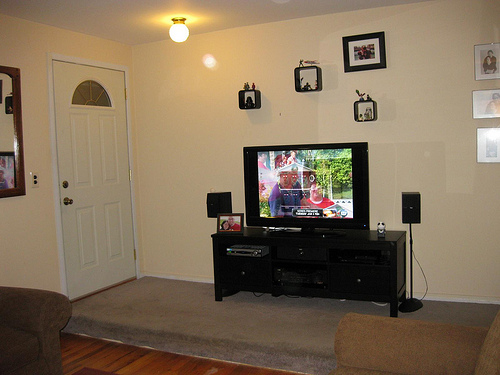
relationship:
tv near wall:
[243, 143, 369, 234] [133, 1, 498, 303]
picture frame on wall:
[340, 31, 387, 71] [133, 1, 498, 303]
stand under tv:
[210, 231, 408, 317] [243, 143, 369, 234]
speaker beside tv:
[401, 191, 423, 312] [243, 143, 369, 234]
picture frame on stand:
[216, 213, 243, 236] [210, 231, 408, 317]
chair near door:
[2, 286, 71, 374] [54, 61, 138, 300]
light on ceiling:
[169, 16, 191, 44] [1, 1, 414, 43]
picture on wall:
[474, 42, 500, 80] [133, 1, 498, 303]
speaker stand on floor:
[405, 225, 422, 312] [60, 275, 497, 374]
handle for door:
[65, 198, 74, 205] [54, 61, 138, 300]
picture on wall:
[474, 91, 498, 118] [133, 1, 498, 303]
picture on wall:
[477, 126, 500, 161] [133, 1, 498, 303]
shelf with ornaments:
[239, 88, 261, 111] [244, 97, 254, 108]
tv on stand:
[243, 143, 369, 234] [210, 231, 408, 317]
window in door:
[72, 80, 111, 106] [54, 61, 138, 300]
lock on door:
[64, 180, 70, 187] [54, 61, 138, 300]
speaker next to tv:
[401, 191, 423, 312] [243, 143, 369, 234]